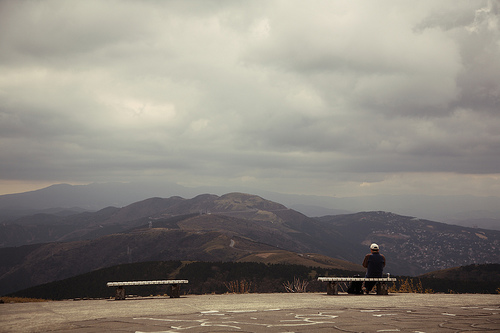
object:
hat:
[370, 242, 380, 249]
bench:
[105, 278, 190, 300]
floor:
[0, 291, 500, 333]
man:
[361, 241, 388, 294]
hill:
[0, 257, 500, 299]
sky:
[0, 0, 500, 232]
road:
[229, 239, 247, 252]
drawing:
[0, 302, 500, 332]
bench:
[316, 276, 398, 295]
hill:
[0, 191, 345, 244]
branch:
[280, 275, 311, 293]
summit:
[169, 195, 185, 199]